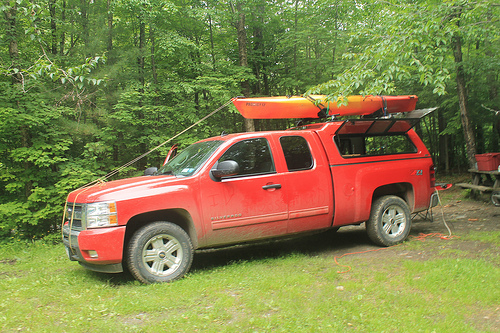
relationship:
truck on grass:
[66, 123, 446, 252] [205, 261, 458, 321]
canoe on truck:
[229, 86, 422, 122] [66, 123, 446, 252]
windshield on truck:
[177, 141, 210, 166] [66, 123, 446, 252]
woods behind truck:
[38, 16, 417, 94] [66, 123, 446, 252]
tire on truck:
[137, 226, 192, 288] [66, 123, 446, 252]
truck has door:
[66, 123, 446, 252] [224, 177, 300, 230]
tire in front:
[137, 226, 192, 288] [21, 174, 148, 316]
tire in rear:
[373, 192, 416, 251] [427, 125, 459, 302]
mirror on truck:
[208, 160, 247, 181] [66, 123, 446, 252]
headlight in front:
[99, 202, 124, 230] [21, 174, 148, 316]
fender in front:
[52, 232, 123, 263] [21, 174, 148, 316]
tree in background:
[81, 13, 144, 168] [23, 11, 495, 109]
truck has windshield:
[66, 123, 446, 252] [177, 141, 210, 166]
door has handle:
[224, 177, 300, 230] [263, 179, 288, 195]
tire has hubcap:
[373, 192, 416, 251] [387, 211, 405, 233]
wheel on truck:
[137, 226, 192, 288] [66, 123, 446, 252]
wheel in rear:
[373, 192, 416, 251] [427, 125, 459, 302]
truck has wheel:
[66, 123, 446, 252] [373, 192, 416, 251]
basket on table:
[462, 148, 498, 179] [455, 152, 500, 199]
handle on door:
[263, 179, 288, 195] [224, 177, 300, 230]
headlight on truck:
[99, 202, 124, 230] [66, 123, 446, 252]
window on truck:
[280, 133, 321, 179] [66, 123, 446, 252]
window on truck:
[223, 145, 277, 188] [66, 123, 446, 252]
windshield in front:
[177, 141, 210, 166] [21, 174, 148, 316]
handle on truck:
[263, 179, 288, 195] [66, 123, 446, 252]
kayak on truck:
[229, 86, 422, 122] [66, 123, 446, 252]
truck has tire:
[66, 123, 446, 252] [137, 226, 192, 288]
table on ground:
[455, 152, 500, 199] [415, 187, 499, 332]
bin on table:
[476, 142, 498, 167] [455, 152, 500, 199]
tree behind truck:
[81, 13, 144, 168] [66, 123, 446, 252]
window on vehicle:
[280, 133, 321, 179] [66, 123, 446, 252]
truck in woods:
[66, 123, 446, 252] [38, 16, 417, 94]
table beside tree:
[455, 152, 500, 199] [439, 28, 484, 156]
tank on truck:
[344, 179, 364, 204] [66, 123, 446, 252]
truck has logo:
[66, 123, 446, 252] [61, 215, 72, 229]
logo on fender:
[61, 215, 72, 229] [52, 232, 123, 263]